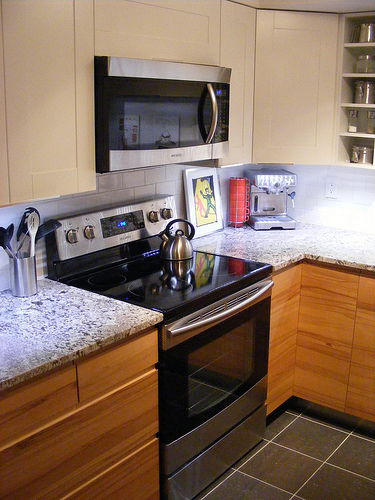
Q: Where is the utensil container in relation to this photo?
A: Middle-right hand side.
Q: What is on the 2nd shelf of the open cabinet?
A: Salt and pepper shakers.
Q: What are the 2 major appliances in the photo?
A: New stove and microwave.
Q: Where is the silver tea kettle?
A: Top right burner of the stove.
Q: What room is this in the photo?
A: Kitchen.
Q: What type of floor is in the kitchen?
A: Dark gray slate tile.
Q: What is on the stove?
A: Teapot.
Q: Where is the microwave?
A: Above stove.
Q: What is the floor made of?
A: Tile.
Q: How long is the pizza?
A: No pizza.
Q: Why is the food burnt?
A: No food.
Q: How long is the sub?
A: No sub.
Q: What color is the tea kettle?
A: Black and silver.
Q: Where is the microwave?
A: Above the stove.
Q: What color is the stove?
A: Silver and black.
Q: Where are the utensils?
A: On the counter.